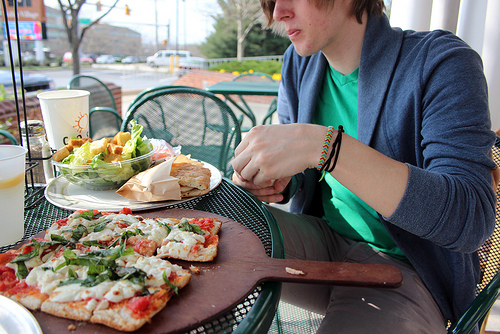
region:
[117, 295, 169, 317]
sauce is red color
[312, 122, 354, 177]
bracelets on the wrist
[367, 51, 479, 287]
cardigan is blue color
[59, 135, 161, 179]
croutons in the salad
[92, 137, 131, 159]
croutons are brown color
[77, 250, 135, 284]
spinach on the pizza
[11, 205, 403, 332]
dark brown wood pizza board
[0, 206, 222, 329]
small square pizza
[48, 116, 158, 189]
caesar salad in a clear bowl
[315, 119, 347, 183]
two bracelets on a wrist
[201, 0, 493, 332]
man wearing a blue jacket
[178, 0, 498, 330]
man wearing two bracelets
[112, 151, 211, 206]
small sandwich in a paper bag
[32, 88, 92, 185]
tall paper beverage cup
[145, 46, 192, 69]
white van driving on the road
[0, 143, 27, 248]
plastic cup of water with lemon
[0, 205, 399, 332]
Pizza on a wooden paddle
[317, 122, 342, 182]
Two bracelets on woman's wrist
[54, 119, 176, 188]
Salad in a plastic bowl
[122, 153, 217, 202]
Sandwich in a bag on a plate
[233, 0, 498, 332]
Woman sitting at an outdoor table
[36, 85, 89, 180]
Paper beverage cup on the table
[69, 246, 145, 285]
Pieces of spinach on the pizza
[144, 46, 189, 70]
Van on the road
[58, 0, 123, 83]
Bare tree along the sidewalk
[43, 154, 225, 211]
White plate under the salad and sandwich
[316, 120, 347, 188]
Bracelets around a wrist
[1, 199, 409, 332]
Pizza on a wooden tray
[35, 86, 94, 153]
A tall white paper cup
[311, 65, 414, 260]
A green colored shirt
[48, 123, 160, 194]
Salad in a plastic container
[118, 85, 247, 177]
A green colored chair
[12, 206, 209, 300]
Green veggies on the pizza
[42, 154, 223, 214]
A white round plate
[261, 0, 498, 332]
Person wearing a blue sweater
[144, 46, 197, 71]
The van is white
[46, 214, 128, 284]
green veggies on pizza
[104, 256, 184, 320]
a square slice of pizza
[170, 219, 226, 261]
a square slice of pizza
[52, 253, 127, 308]
a square slice of pizza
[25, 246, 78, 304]
a square slice of pizza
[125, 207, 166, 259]
a square slice of pizza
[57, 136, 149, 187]
a salad on plate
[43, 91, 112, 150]
the cup is white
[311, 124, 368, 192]
the bracelet is black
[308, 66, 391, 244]
the shirt is green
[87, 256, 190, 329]
pizza slice next to pizza slice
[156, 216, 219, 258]
pizza slice next to pizza slice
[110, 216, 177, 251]
pizza slice next to pizza slice